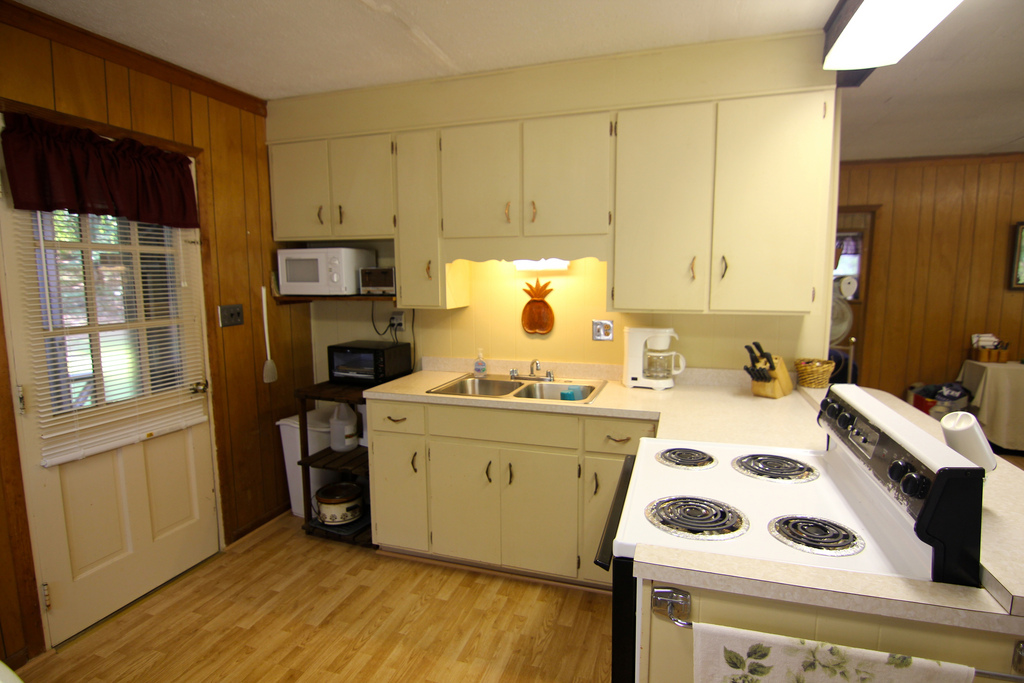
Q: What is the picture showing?
A: It is showing a kitchen.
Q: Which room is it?
A: It is a kitchen.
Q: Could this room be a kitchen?
A: Yes, it is a kitchen.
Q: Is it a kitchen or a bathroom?
A: It is a kitchen.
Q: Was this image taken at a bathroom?
A: No, the picture was taken in a kitchen.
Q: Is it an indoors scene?
A: Yes, it is indoors.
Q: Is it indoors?
A: Yes, it is indoors.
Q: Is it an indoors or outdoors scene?
A: It is indoors.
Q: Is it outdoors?
A: No, it is indoors.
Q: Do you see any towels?
A: Yes, there is a towel.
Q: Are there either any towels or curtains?
A: Yes, there is a towel.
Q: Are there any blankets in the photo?
A: No, there are no blankets.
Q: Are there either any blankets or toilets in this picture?
A: No, there are no blankets or toilets.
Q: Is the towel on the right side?
A: Yes, the towel is on the right of the image.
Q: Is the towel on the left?
A: No, the towel is on the right of the image.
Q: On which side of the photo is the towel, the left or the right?
A: The towel is on the right of the image.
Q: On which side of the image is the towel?
A: The towel is on the right of the image.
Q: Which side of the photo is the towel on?
A: The towel is on the right of the image.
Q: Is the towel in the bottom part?
A: Yes, the towel is in the bottom of the image.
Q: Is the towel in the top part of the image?
A: No, the towel is in the bottom of the image.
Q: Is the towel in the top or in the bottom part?
A: The towel is in the bottom of the image.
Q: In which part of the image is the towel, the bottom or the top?
A: The towel is in the bottom of the image.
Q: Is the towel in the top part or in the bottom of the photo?
A: The towel is in the bottom of the image.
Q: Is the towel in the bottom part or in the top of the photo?
A: The towel is in the bottom of the image.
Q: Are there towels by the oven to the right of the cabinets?
A: Yes, there is a towel by the oven.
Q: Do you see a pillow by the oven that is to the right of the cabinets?
A: No, there is a towel by the oven.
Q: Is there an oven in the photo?
A: Yes, there is an oven.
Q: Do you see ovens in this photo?
A: Yes, there is an oven.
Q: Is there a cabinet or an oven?
A: Yes, there is an oven.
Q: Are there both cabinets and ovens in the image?
A: Yes, there are both an oven and a cabinet.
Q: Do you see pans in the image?
A: No, there are no pans.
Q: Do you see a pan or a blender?
A: No, there are no pans or blenders.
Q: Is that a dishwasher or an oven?
A: That is an oven.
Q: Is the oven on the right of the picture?
A: Yes, the oven is on the right of the image.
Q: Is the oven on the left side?
A: No, the oven is on the right of the image.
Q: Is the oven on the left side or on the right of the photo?
A: The oven is on the right of the image.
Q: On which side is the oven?
A: The oven is on the right of the image.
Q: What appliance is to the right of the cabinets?
A: The appliance is an oven.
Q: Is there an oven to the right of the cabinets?
A: Yes, there is an oven to the right of the cabinets.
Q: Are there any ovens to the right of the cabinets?
A: Yes, there is an oven to the right of the cabinets.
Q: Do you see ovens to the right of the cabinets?
A: Yes, there is an oven to the right of the cabinets.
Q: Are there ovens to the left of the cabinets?
A: No, the oven is to the right of the cabinets.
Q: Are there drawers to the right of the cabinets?
A: No, there is an oven to the right of the cabinets.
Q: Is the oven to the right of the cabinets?
A: Yes, the oven is to the right of the cabinets.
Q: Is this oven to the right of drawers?
A: No, the oven is to the right of the cabinets.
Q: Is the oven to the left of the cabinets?
A: No, the oven is to the right of the cabinets.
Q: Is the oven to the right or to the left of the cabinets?
A: The oven is to the right of the cabinets.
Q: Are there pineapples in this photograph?
A: Yes, there is a pineapple.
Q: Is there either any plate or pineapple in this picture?
A: Yes, there is a pineapple.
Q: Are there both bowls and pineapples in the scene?
A: No, there is a pineapple but no bowls.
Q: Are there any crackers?
A: No, there are no crackers.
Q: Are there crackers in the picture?
A: No, there are no crackers.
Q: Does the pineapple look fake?
A: Yes, the pineapple is fake.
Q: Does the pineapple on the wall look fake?
A: Yes, the pineapple is fake.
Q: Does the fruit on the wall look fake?
A: Yes, the pineapple is fake.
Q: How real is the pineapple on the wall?
A: The pineapple is fake.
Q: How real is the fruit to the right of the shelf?
A: The pineapple is fake.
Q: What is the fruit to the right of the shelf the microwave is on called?
A: The fruit is a pineapple.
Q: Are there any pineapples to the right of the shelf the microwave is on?
A: Yes, there is a pineapple to the right of the shelf.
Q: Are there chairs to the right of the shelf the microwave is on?
A: No, there is a pineapple to the right of the shelf.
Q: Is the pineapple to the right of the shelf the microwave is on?
A: Yes, the pineapple is to the right of the shelf.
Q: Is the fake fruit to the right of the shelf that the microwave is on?
A: Yes, the pineapple is to the right of the shelf.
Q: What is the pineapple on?
A: The pineapple is on the wall.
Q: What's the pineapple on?
A: The pineapple is on the wall.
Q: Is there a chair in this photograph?
A: No, there are no chairs.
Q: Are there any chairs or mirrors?
A: No, there are no chairs or mirrors.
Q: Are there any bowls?
A: No, there are no bowls.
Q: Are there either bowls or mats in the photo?
A: No, there are no bowls or mats.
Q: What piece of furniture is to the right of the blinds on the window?
A: The piece of furniture is a shelf.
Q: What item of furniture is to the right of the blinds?
A: The piece of furniture is a shelf.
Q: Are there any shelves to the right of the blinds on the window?
A: Yes, there is a shelf to the right of the blinds.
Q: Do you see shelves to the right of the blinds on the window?
A: Yes, there is a shelf to the right of the blinds.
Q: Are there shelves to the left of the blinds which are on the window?
A: No, the shelf is to the right of the blinds.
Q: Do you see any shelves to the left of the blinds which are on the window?
A: No, the shelf is to the right of the blinds.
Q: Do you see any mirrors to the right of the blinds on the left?
A: No, there is a shelf to the right of the blinds.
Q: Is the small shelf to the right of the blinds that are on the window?
A: Yes, the shelf is to the right of the blinds.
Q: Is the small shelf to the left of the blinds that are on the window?
A: No, the shelf is to the right of the blinds.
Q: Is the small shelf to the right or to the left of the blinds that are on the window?
A: The shelf is to the right of the blinds.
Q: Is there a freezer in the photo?
A: No, there are no refrigerators.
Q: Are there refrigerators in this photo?
A: No, there are no refrigerators.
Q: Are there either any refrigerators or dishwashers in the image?
A: No, there are no refrigerators or dishwashers.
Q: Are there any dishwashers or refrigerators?
A: No, there are no refrigerators or dishwashers.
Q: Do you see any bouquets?
A: No, there are no bouquets.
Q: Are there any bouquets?
A: No, there are no bouquets.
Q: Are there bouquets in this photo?
A: No, there are no bouquets.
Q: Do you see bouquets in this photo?
A: No, there are no bouquets.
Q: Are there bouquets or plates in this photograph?
A: No, there are no bouquets or plates.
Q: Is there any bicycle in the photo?
A: No, there are no bicycles.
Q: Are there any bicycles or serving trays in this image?
A: No, there are no bicycles or serving trays.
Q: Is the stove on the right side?
A: Yes, the stove is on the right of the image.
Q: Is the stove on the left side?
A: No, the stove is on the right of the image.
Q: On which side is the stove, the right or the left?
A: The stove is on the right of the image.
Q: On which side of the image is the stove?
A: The stove is on the right of the image.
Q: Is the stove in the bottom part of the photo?
A: Yes, the stove is in the bottom of the image.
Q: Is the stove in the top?
A: No, the stove is in the bottom of the image.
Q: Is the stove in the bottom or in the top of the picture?
A: The stove is in the bottom of the image.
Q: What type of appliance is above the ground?
A: The appliance is a stove.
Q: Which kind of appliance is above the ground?
A: The appliance is a stove.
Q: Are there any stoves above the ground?
A: Yes, there is a stove above the ground.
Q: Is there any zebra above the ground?
A: No, there is a stove above the ground.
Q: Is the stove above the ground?
A: Yes, the stove is above the ground.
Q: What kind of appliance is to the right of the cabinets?
A: The appliance is a stove.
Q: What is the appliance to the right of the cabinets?
A: The appliance is a stove.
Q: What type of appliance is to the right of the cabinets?
A: The appliance is a stove.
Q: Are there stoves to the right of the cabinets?
A: Yes, there is a stove to the right of the cabinets.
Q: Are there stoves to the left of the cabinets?
A: No, the stove is to the right of the cabinets.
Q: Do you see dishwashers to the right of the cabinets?
A: No, there is a stove to the right of the cabinets.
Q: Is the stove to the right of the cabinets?
A: Yes, the stove is to the right of the cabinets.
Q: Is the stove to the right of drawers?
A: No, the stove is to the right of the cabinets.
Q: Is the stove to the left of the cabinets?
A: No, the stove is to the right of the cabinets.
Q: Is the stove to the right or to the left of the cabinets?
A: The stove is to the right of the cabinets.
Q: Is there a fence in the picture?
A: No, there are no fences.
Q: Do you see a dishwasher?
A: No, there are no dishwashers.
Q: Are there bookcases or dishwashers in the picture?
A: No, there are no dishwashers or bookcases.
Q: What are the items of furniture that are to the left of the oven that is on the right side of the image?
A: The pieces of furniture are cabinets.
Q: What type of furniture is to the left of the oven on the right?
A: The pieces of furniture are cabinets.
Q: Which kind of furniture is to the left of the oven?
A: The pieces of furniture are cabinets.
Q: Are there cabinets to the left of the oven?
A: Yes, there are cabinets to the left of the oven.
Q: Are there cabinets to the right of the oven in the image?
A: No, the cabinets are to the left of the oven.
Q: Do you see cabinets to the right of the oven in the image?
A: No, the cabinets are to the left of the oven.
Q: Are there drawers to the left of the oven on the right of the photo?
A: No, there are cabinets to the left of the oven.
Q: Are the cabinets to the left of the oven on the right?
A: Yes, the cabinets are to the left of the oven.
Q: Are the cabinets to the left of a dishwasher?
A: No, the cabinets are to the left of the oven.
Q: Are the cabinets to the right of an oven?
A: No, the cabinets are to the left of an oven.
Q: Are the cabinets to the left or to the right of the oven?
A: The cabinets are to the left of the oven.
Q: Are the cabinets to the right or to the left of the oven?
A: The cabinets are to the left of the oven.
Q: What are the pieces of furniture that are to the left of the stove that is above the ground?
A: The pieces of furniture are cabinets.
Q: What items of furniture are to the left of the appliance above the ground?
A: The pieces of furniture are cabinets.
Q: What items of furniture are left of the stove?
A: The pieces of furniture are cabinets.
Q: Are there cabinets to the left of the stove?
A: Yes, there are cabinets to the left of the stove.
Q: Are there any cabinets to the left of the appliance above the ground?
A: Yes, there are cabinets to the left of the stove.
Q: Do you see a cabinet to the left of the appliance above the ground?
A: Yes, there are cabinets to the left of the stove.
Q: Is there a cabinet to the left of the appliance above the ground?
A: Yes, there are cabinets to the left of the stove.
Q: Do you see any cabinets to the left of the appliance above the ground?
A: Yes, there are cabinets to the left of the stove.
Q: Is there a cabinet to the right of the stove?
A: No, the cabinets are to the left of the stove.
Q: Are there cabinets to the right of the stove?
A: No, the cabinets are to the left of the stove.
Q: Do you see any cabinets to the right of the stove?
A: No, the cabinets are to the left of the stove.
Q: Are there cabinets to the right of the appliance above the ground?
A: No, the cabinets are to the left of the stove.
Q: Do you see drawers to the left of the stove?
A: No, there are cabinets to the left of the stove.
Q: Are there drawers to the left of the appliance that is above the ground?
A: No, there are cabinets to the left of the stove.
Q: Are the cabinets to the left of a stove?
A: Yes, the cabinets are to the left of a stove.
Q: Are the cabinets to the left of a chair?
A: No, the cabinets are to the left of a stove.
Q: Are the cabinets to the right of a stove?
A: No, the cabinets are to the left of a stove.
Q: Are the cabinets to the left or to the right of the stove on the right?
A: The cabinets are to the left of the stove.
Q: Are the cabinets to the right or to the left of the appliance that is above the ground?
A: The cabinets are to the left of the stove.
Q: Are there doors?
A: Yes, there is a door.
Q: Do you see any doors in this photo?
A: Yes, there is a door.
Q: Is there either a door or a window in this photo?
A: Yes, there is a door.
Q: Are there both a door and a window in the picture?
A: Yes, there are both a door and a window.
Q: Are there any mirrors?
A: No, there are no mirrors.